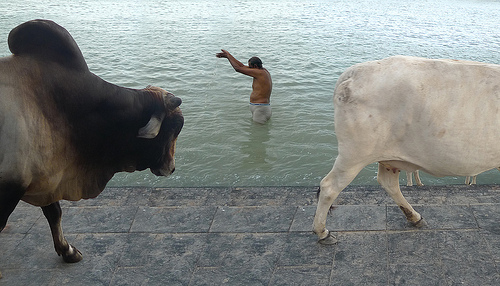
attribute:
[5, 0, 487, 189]
water — large body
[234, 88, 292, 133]
underware — white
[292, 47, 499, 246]
animal — white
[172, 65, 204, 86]
ripples — small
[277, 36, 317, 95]
ripples — small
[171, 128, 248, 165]
water — large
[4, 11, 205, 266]
animal — Black 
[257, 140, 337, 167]
ripples — small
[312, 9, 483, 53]
water — large, blue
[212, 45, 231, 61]
hands — open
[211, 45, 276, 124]
man — extended arms